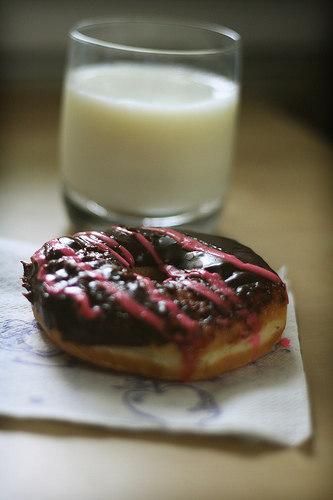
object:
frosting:
[19, 223, 289, 349]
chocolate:
[238, 260, 278, 304]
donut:
[19, 222, 290, 383]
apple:
[120, 377, 218, 426]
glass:
[56, 14, 242, 236]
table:
[0, 86, 332, 499]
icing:
[20, 223, 288, 349]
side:
[206, 278, 282, 330]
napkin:
[0, 234, 312, 445]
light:
[199, 245, 224, 268]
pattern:
[0, 311, 59, 357]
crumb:
[262, 350, 284, 372]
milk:
[61, 65, 239, 217]